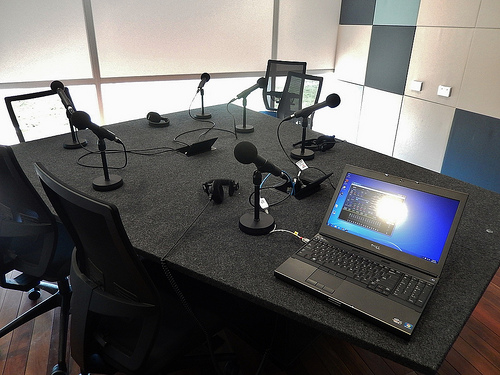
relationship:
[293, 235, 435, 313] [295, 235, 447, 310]
keyboard on lap top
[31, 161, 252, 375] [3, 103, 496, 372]
chair by desk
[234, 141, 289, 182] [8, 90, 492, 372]
microphone on table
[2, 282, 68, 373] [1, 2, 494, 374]
floor of office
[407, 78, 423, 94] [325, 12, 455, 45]
thermostat mounted on wall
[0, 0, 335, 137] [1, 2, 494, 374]
wall of office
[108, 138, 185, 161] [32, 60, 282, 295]
cords on table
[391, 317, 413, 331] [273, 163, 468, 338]
logo on laptop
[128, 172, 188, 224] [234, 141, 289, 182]
desk full of microphone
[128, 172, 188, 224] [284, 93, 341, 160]
desk full of microphone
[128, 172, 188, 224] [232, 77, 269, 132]
desk full of microphone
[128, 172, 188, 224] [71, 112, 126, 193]
desk full of microphone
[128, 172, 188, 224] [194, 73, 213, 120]
desk full of microphone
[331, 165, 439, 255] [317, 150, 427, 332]
screen of lap top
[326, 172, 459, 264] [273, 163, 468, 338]
screen of laptop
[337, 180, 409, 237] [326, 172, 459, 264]
document on screen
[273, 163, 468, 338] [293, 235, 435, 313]
laptop has keyboard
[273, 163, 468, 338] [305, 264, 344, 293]
laptop has pad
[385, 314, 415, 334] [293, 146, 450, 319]
logo on lap top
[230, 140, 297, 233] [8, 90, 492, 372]
microphone on table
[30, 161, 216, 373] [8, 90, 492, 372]
chair next to table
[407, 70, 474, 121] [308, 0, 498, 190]
switch attached to wall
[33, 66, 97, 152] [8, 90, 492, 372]
microphone on table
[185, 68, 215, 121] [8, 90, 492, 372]
microphone on table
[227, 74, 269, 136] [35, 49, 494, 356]
microphone on table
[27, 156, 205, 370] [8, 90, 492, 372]
chair next to table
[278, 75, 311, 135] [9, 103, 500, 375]
chair next to desk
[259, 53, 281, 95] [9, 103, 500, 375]
chair next to desk